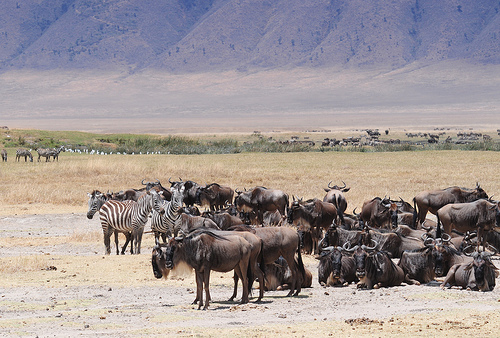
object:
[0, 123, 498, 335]
field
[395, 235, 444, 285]
wildebeest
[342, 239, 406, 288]
wildebeest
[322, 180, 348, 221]
wildebeest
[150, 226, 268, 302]
animal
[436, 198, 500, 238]
animal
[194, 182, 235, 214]
wildebeast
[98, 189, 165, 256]
zebras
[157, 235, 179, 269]
head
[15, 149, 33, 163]
animals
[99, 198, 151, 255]
body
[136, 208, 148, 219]
stripes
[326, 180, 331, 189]
horns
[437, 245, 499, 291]
wildebeast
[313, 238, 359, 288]
wildebeest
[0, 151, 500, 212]
grass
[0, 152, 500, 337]
ground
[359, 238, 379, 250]
horns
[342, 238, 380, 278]
head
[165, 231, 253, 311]
animals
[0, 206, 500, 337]
dirt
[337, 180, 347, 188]
horn